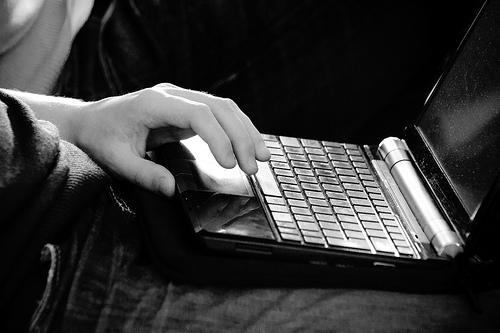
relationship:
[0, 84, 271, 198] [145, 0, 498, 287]
hand hovering over laptop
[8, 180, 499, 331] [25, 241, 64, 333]
pants has pocket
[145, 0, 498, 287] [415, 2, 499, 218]
laptop has screen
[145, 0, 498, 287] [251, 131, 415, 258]
laptop has keyboard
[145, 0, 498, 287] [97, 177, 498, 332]
laptop sitting on lap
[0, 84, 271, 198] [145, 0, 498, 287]
hand touching laptop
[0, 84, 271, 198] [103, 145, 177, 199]
hand has thumb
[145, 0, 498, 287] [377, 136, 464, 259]
laptop has hinge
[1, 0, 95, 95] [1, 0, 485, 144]
cloth in background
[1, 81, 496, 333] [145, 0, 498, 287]
man has laptop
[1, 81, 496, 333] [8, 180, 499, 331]
man has pants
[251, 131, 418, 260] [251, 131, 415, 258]
keys on keyboard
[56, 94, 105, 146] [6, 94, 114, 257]
wrist resting on stomach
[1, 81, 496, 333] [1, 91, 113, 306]
man has sweater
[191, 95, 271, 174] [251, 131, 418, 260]
fingers touching keys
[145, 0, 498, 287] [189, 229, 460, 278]
laptop has edge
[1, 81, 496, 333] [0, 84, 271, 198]
man has left hand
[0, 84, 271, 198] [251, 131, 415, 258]
left hand above keyboard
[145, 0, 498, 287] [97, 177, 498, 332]
laptop on lap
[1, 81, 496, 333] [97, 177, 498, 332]
man has lap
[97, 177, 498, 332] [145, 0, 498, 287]
lap holding laptop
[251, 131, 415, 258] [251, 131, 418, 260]
keyboard has keys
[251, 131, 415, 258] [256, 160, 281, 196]
keyboard has space bar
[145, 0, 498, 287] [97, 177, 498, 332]
laptop on a lap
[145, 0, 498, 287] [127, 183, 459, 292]
laptop has bag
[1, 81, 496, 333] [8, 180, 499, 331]
man wearing pants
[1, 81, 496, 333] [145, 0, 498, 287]
man holding laptop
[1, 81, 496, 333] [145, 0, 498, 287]
man using laptop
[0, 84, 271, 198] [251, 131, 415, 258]
hand typing on keyboard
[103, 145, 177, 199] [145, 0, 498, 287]
thumb touching laptop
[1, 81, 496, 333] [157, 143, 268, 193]
man has nails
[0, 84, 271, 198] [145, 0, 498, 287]
hand on laptop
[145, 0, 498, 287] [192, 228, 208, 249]
laptop has corner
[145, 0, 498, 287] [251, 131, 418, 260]
laptop has keys